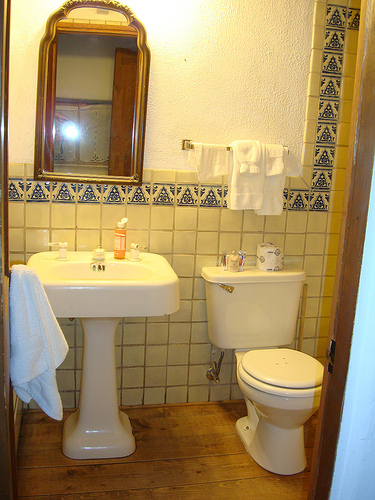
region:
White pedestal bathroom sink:
[18, 245, 182, 459]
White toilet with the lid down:
[199, 267, 336, 490]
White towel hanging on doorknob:
[3, 254, 79, 438]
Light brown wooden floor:
[135, 406, 241, 495]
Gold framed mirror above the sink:
[34, 3, 157, 194]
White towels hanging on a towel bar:
[179, 130, 300, 223]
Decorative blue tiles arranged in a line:
[305, 42, 343, 164]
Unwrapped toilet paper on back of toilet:
[252, 239, 304, 278]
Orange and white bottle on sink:
[110, 215, 134, 266]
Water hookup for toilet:
[194, 352, 233, 391]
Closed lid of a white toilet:
[235, 347, 323, 397]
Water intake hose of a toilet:
[204, 343, 230, 387]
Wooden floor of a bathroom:
[20, 459, 240, 499]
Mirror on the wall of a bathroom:
[27, 0, 149, 188]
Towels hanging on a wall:
[176, 137, 299, 210]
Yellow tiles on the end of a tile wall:
[317, 27, 354, 396]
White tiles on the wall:
[143, 214, 227, 249]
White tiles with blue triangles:
[12, 175, 332, 218]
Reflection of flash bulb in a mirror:
[58, 118, 86, 146]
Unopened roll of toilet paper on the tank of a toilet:
[255, 241, 286, 276]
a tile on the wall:
[123, 387, 143, 404]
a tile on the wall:
[143, 386, 164, 402]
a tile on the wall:
[166, 385, 187, 405]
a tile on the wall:
[187, 385, 210, 401]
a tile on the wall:
[212, 383, 229, 400]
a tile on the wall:
[122, 365, 143, 385]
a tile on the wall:
[145, 365, 166, 388]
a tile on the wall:
[167, 364, 185, 384]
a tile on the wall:
[190, 362, 208, 383]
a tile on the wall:
[120, 343, 145, 370]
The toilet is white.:
[197, 235, 325, 475]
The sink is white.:
[7, 210, 176, 456]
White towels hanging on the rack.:
[183, 125, 290, 223]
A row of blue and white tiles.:
[303, 0, 349, 210]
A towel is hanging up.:
[4, 262, 66, 424]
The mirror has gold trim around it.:
[31, 0, 152, 189]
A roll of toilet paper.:
[251, 225, 292, 270]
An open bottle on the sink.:
[108, 210, 130, 258]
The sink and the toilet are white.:
[19, 215, 326, 470]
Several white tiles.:
[129, 323, 189, 399]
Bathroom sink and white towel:
[32, 214, 190, 342]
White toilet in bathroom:
[200, 266, 311, 490]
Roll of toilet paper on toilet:
[255, 231, 304, 288]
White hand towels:
[183, 126, 296, 227]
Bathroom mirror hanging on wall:
[31, 10, 157, 214]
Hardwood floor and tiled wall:
[140, 375, 220, 460]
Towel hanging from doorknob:
[5, 251, 69, 432]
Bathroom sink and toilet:
[68, 224, 295, 347]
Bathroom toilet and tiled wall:
[190, 261, 250, 353]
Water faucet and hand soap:
[33, 226, 161, 266]